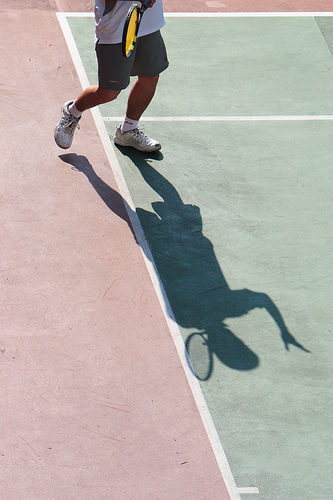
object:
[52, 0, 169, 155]
tennis player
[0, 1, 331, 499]
court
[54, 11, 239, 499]
line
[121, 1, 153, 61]
racket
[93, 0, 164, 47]
shirt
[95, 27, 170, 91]
shorts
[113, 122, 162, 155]
shoe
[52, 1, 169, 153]
person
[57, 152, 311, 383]
shadow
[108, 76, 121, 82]
logo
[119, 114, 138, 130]
sock